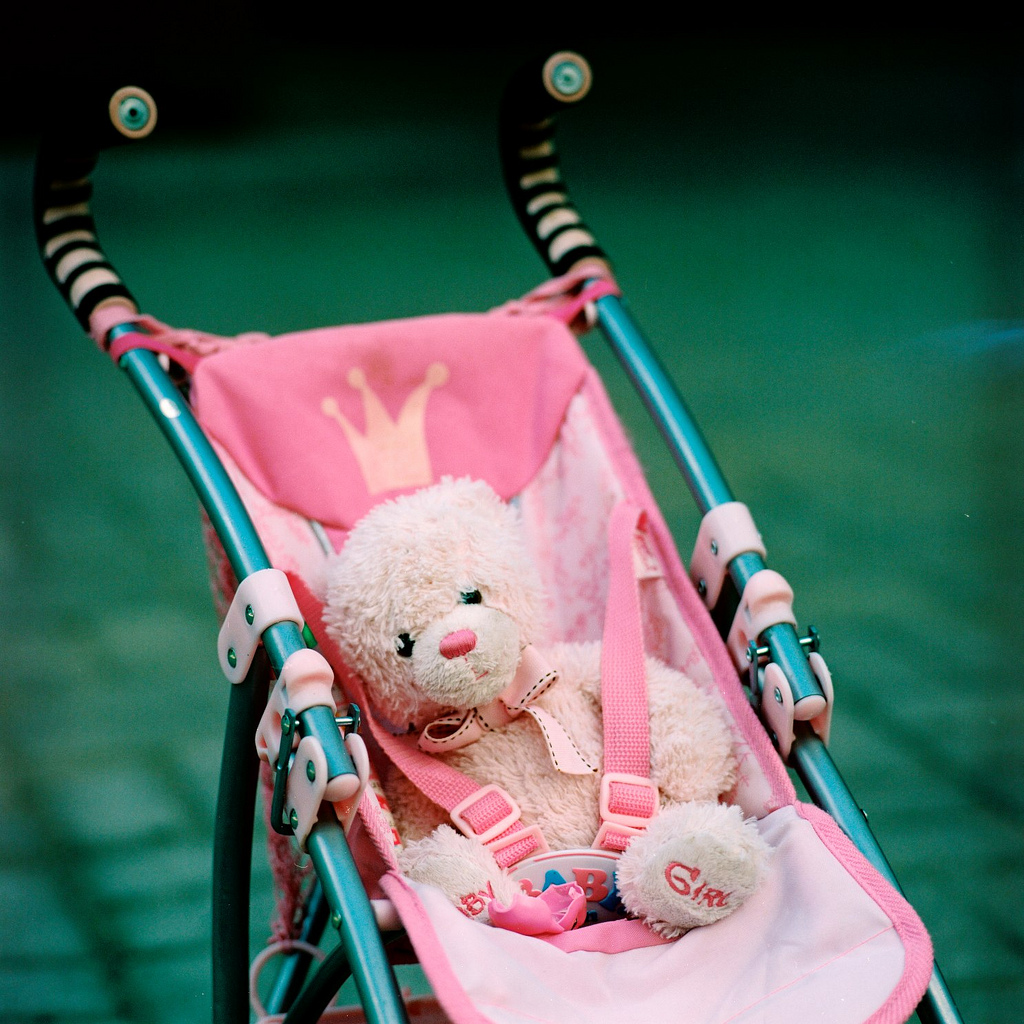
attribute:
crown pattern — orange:
[321, 352, 455, 502]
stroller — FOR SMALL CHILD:
[51, 41, 965, 1022]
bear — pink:
[285, 473, 770, 957]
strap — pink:
[284, 568, 553, 873]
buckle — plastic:
[455, 778, 546, 871]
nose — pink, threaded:
[434, 628, 478, 661]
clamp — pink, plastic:
[213, 568, 311, 685]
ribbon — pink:
[408, 641, 594, 789]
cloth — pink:
[190, 305, 931, 1021]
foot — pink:
[401, 829, 544, 938]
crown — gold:
[311, 352, 450, 497]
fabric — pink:
[183, 302, 940, 1022]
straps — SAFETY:
[593, 510, 650, 856]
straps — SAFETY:
[318, 619, 552, 866]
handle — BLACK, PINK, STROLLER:
[491, 39, 610, 277]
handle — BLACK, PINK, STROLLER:
[14, 67, 164, 322]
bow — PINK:
[413, 646, 612, 776]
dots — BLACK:
[526, 681, 537, 694]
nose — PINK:
[433, 621, 481, 660]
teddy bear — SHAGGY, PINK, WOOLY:
[309, 452, 757, 934]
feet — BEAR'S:
[400, 804, 764, 934]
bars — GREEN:
[117, 338, 355, 803]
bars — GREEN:
[590, 296, 817, 700]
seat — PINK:
[102, 258, 941, 1006]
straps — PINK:
[301, 506, 654, 889]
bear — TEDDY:
[320, 467, 757, 941]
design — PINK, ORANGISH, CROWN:
[314, 348, 472, 498]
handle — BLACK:
[489, 33, 619, 275]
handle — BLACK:
[22, 61, 163, 312]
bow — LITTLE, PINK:
[413, 627, 608, 790]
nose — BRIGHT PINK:
[433, 618, 483, 660]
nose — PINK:
[428, 623, 491, 665]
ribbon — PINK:
[409, 642, 606, 794]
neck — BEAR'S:
[415, 647, 571, 738]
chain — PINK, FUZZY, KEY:
[243, 754, 336, 1005]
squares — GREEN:
[35, 748, 193, 857]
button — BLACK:
[456, 580, 496, 613]